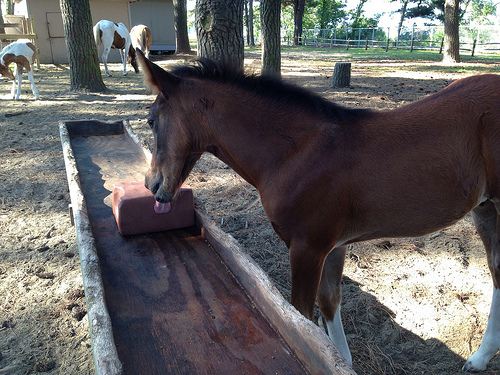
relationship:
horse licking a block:
[130, 54, 419, 294] [107, 178, 197, 242]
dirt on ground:
[417, 289, 456, 319] [397, 290, 425, 329]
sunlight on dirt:
[397, 273, 449, 350] [381, 270, 465, 350]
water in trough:
[142, 293, 190, 333] [117, 257, 219, 357]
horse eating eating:
[88, 18, 152, 77] [117, 64, 143, 89]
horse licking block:
[130, 54, 419, 294] [112, 178, 195, 237]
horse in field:
[130, 54, 419, 294] [13, 211, 63, 283]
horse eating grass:
[88, 9, 180, 92] [108, 62, 146, 113]